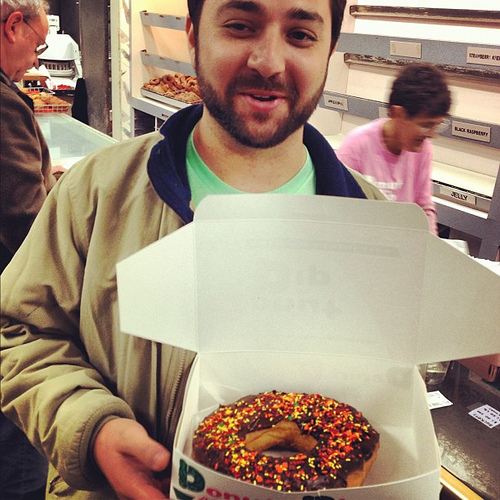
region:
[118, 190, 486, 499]
the opened donut box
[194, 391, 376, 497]
the big donut in the box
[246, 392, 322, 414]
the sprinkles on the donut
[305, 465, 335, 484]
the chocolate on the donut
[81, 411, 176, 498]
the man's right hand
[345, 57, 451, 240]
the woman behind the counter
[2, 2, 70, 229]
the older man at the counter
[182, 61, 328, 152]
the man's beard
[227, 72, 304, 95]
the man's mustache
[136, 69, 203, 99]
the donuts on the shelf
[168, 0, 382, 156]
The man is smiling.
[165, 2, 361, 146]
The man has hair.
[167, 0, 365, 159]
Man's hair is dark.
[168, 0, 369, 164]
The man has a moustache.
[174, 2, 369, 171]
The man has a beard.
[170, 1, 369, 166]
The moustache is trim.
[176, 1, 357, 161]
The beard is trim.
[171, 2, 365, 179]
The man has eyes.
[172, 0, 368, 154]
Man's eyes are open.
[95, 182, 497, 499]
The donut is large.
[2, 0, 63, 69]
man is wearing glasses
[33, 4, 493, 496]
man is holding white box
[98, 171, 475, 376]
top of box is open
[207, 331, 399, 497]
donut has chocolate icing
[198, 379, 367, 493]
sprinkles on top of donut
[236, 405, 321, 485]
donut has hole in center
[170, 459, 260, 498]
green and red letters on box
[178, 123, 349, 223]
man's shirt is green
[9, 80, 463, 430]
man's jacket is brown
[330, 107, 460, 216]
woman's shirt is pink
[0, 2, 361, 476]
man holding a box with a big donut on it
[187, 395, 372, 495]
big chocolate donut with chips on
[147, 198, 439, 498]
white open box with a big donut on it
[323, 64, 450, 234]
old woman with pink t-shirt in the right side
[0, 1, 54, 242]
man in profile with brown jacket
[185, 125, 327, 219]
part of a green t-shhirt in a man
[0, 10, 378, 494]
man with a brown jacket holding a box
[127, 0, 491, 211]
white large fridge behind people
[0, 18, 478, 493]
three people in a supermarket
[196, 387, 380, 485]
big donut in a white box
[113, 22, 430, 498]
this guy has a huge donut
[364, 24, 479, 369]
a woman wearing pink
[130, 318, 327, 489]
the donut is in a box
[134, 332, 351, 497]
the donut has sprinkles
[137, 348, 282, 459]
the donut has chocolate frosting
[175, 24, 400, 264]
the man has a green shirt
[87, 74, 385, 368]
the jacket is tan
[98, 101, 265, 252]
the jacket lining is navy blue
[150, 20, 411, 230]
this man has a beard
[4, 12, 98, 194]
this man has glasses